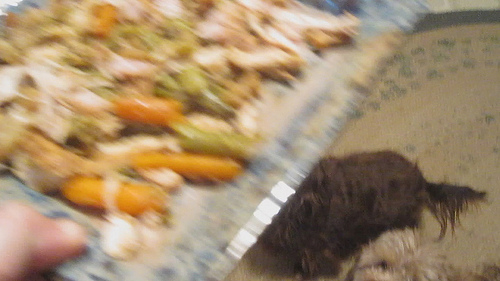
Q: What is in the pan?
A: A pan full of food.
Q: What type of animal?
A: A dark brown dog.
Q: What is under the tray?
A: A dog is going under the tray.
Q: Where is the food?
A: On a silver tray.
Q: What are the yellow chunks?
A: The yellow chunks are food.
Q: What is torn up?
A: The pieces of meat.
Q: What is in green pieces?
A: The green pieces of food.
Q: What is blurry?
A: The food is blurry.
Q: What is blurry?
A: The blurry food on plate.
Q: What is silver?
A: The edge of the silver plate.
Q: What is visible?
A: Brown and tan thing.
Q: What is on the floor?
A: Dark brown dog.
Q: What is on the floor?
A: Oval rug.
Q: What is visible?
A: Piece of food.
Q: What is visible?
A: Piece of food.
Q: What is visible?
A: Piece of food.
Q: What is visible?
A: Piece of food.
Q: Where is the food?
A: On a silver tray.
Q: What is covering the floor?
A: Carpet.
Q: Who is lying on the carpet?
A: Dog.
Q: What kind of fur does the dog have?
A: Brown and shaggy.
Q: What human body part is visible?
A: Thumb.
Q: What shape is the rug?
A: Oval.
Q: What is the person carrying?
A: Tray of food.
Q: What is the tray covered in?
A: Foil.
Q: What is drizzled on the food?
A: White sauce.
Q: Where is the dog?
A: On the carpet.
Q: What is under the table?
A: An animal.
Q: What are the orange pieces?
A: Carrots.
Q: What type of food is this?
A: A stir fry.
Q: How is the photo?
A: Blurry.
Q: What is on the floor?
A: Animal.